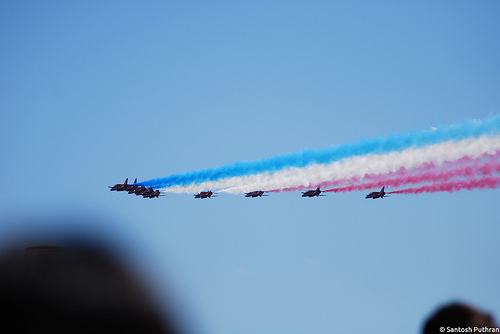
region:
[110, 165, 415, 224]
planes in formation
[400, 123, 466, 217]
smoke from planes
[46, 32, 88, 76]
white clouds in blue sky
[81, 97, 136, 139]
white clouds in blue sky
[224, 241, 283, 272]
white clouds in blue sky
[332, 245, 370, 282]
white clouds in blue sky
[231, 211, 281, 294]
white clouds in blue sky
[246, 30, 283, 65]
white clouds in blue sky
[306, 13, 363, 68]
white clouds in blue sky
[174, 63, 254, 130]
white clouds in blue sky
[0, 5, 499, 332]
the bright blue cloudless sky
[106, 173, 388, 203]
the jets flying in formation in the sky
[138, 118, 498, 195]
the colorful streams of smoke behind the jets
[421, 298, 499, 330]
the top of someone's head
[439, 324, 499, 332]
the writing in the corner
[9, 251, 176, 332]
the top of another person's head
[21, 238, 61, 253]
the top of some kind of tower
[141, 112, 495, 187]
the blue streams of smoke behind three of the jets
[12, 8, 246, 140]
a big patch of blue sky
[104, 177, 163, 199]
the jets that look like they are close together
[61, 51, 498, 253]
The airplanes are flying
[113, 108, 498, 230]
There are streams behind the jet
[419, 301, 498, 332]
There are white texts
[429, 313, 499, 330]
Texts in the corner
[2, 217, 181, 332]
This person is blurry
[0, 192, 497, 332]
People are watching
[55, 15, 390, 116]
Blue is the color of the sky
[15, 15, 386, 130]
Daytime is the time of day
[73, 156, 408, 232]
These are black jets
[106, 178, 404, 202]
several jets in the sky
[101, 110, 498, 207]
jets leaving trails of colored smoke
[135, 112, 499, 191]
trail of blue smoke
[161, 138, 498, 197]
trail of white smole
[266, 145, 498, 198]
trails of red smoke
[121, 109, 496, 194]
the colors of the american flag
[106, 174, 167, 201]
jets flying close together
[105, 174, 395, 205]
jets flying fast through the sky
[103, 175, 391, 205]
jets have wings and tails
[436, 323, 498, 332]
name of the photographer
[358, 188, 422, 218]
Large jet flying in sky.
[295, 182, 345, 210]
Dark colored jet flying in sky.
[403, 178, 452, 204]
Red smoke coming out of jet.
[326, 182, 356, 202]
Red smoke coming out of jet.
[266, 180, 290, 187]
White smoke coming out of jet.